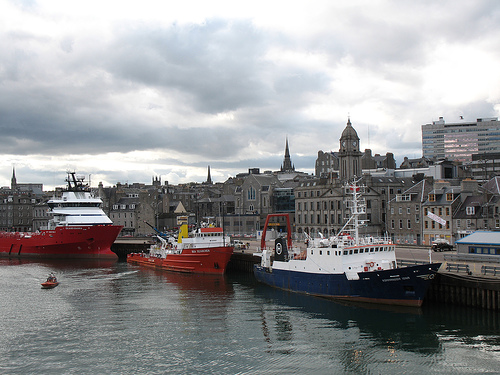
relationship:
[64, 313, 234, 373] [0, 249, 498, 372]
ripples in water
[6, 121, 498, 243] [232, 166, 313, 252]
window in building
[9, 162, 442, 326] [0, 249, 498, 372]
boat in water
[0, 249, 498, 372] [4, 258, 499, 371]
water in forefront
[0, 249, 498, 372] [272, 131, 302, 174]
steeple in background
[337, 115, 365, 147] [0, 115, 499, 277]
top on building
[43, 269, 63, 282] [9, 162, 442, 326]
person on boat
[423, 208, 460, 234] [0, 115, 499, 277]
sign on building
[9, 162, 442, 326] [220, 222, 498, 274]
vehicle on road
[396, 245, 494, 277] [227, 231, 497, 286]
railing on road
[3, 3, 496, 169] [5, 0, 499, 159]
clouds in sky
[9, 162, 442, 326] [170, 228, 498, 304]
boat docked on port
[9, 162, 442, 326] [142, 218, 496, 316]
boat docked on port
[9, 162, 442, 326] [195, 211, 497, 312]
boat docked on port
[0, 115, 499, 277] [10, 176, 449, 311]
building behind boats